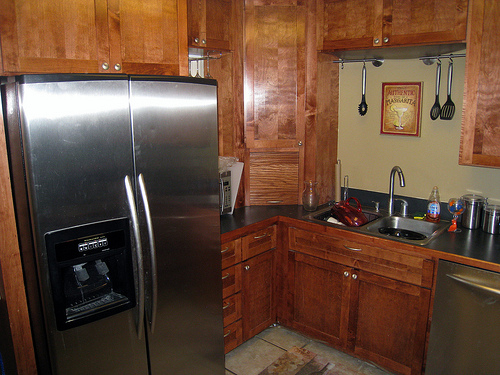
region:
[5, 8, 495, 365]
large metal appliances in wood kitchen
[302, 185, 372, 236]
red pitcher in sink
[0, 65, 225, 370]
refrigerator with double doors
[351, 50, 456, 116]
cooking utensils hanging against wall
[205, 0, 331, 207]
long and short cabinets in corner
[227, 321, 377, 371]
gray tiles under printed rug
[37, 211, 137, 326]
recessed door panel for water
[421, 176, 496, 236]
soap, glass and canisters on counter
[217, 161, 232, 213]
end panel of microwave with buttons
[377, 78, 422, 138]
picture with red border of trophy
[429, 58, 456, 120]
A couple of kitchen utensils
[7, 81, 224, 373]
A large silver refrigerator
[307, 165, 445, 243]
A large kitchen sink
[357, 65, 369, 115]
A pasta strainer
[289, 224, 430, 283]
Wooden drawer under a sink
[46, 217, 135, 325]
Ice cube and cold water maker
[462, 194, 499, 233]
Metal canisters on a counter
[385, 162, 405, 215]
Metal kitchen water spigot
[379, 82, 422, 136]
A picture on the wall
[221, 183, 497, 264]
Solid black counter-tops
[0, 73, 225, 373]
silver refridgerator in the kitchen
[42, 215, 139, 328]
ice and water dispencer on the refridgerator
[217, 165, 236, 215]
microwave on the kitchen counter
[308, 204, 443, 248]
kitchen sink full of dishes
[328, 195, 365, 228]
red pitcher in the sink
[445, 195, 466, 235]
blue and orange wine glass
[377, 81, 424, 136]
brown and red sign over the sink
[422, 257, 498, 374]
silver dish washer in the kitchen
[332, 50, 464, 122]
utensils hanging above the sink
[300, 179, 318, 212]
clear glass vase next to the sink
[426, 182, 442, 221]
A bottle of dishwashing liquid.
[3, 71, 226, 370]
A stainless steel refrigerator.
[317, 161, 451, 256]
A silver kitchen sink.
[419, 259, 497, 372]
A silver dishwasher.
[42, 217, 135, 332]
A black ice and water dispenser.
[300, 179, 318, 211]
A clear glass vase.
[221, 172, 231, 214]
A silver microwave display.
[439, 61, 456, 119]
A black spatula with a silver handle.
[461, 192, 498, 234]
Silver canisters.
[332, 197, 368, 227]
A red glass jug.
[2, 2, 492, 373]
Brown wooden kitchen cabinets.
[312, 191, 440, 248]
A sink with dishes in it.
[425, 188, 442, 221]
A clear container of dishwashing soap with a blue label.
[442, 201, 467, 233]
A wine glass with a blue and orange design.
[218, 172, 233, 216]
Part of a microwave.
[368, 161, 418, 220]
Silver sink fixtures.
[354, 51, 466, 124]
Kitchen utensils hanging.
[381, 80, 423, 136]
A red and brown picture on the wall.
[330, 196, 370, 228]
A red pitcher.